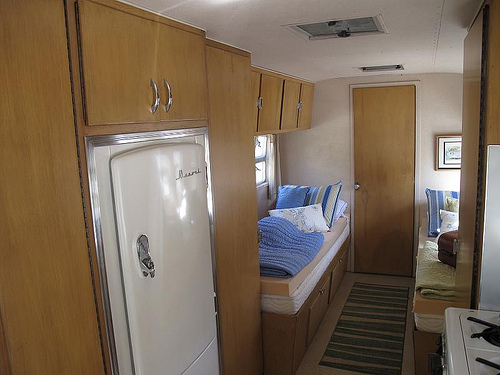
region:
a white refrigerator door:
[108, 139, 220, 373]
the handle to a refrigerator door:
[134, 229, 160, 284]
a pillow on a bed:
[262, 201, 331, 237]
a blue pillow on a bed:
[269, 181, 315, 211]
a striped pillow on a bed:
[303, 181, 346, 223]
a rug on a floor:
[314, 277, 417, 373]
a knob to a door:
[349, 182, 365, 194]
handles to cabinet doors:
[143, 71, 180, 113]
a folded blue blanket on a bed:
[256, 213, 323, 280]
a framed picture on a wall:
[430, 127, 474, 182]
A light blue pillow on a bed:
[273, 183, 312, 210]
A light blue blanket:
[254, 214, 325, 280]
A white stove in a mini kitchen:
[440, 303, 498, 373]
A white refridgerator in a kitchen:
[80, 125, 229, 373]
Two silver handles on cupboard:
[146, 77, 174, 114]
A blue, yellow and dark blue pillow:
[280, 177, 344, 230]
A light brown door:
[350, 85, 418, 276]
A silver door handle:
[352, 183, 360, 190]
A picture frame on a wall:
[432, 131, 463, 171]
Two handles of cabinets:
[140, 72, 177, 114]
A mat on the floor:
[315, 275, 415, 370]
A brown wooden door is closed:
[345, 75, 417, 275]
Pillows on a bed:
[260, 177, 350, 233]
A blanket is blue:
[255, 211, 325, 278]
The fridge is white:
[85, 126, 225, 371]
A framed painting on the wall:
[430, 127, 465, 172]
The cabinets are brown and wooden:
[250, 62, 315, 133]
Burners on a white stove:
[441, 302, 497, 370]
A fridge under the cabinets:
[70, 0, 221, 370]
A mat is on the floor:
[316, 280, 411, 371]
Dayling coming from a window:
[251, 132, 271, 182]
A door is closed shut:
[345, 80, 415, 275]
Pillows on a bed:
[420, 180, 455, 237]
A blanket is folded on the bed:
[410, 235, 455, 300]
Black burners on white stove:
[440, 300, 495, 371]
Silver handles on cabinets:
[140, 72, 172, 112]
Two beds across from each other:
[258, 175, 463, 315]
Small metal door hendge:
[137, 73, 169, 116]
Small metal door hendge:
[158, 73, 178, 119]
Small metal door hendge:
[255, 93, 267, 111]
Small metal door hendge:
[293, 93, 304, 123]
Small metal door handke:
[347, 176, 362, 199]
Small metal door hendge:
[318, 283, 335, 300]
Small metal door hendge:
[335, 258, 347, 270]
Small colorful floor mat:
[314, 265, 407, 372]